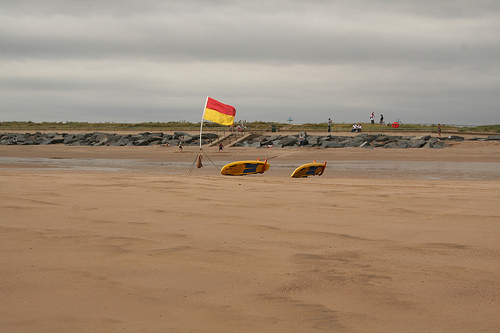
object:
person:
[173, 138, 185, 153]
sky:
[1, 3, 498, 122]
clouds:
[0, 0, 499, 126]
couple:
[367, 109, 386, 123]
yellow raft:
[221, 159, 278, 175]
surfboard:
[219, 158, 271, 173]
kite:
[389, 121, 401, 131]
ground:
[1, 119, 499, 332]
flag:
[196, 97, 237, 153]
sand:
[0, 122, 498, 330]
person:
[378, 113, 386, 125]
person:
[368, 109, 375, 125]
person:
[323, 117, 335, 133]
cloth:
[390, 120, 402, 131]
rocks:
[0, 129, 500, 156]